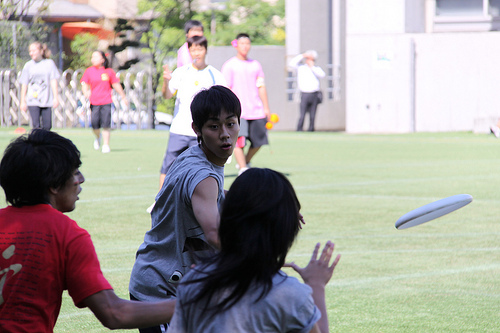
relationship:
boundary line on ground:
[326, 262, 499, 288] [1, 124, 499, 329]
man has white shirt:
[144, 22, 231, 214] [162, 59, 229, 136]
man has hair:
[2, 126, 176, 331] [0, 126, 82, 205]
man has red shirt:
[0, 127, 176, 333] [4, 200, 104, 317]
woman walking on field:
[125, 85, 238, 332] [0, 137, 499, 330]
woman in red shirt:
[80, 49, 129, 150] [78, 64, 118, 106]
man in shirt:
[225, 32, 265, 160] [225, 59, 264, 120]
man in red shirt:
[157, 34, 230, 192] [2, 203, 114, 330]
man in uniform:
[285, 51, 328, 128] [290, 55, 323, 127]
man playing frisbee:
[0, 127, 176, 333] [390, 194, 470, 231]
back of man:
[5, 208, 109, 305] [142, 66, 259, 301]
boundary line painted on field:
[325, 255, 499, 295] [340, 133, 497, 330]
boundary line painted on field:
[350, 240, 495, 256] [340, 133, 497, 330]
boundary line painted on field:
[98, 263, 137, 275] [340, 133, 497, 330]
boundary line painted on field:
[303, 205, 390, 217] [340, 133, 497, 330]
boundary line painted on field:
[298, 192, 433, 203] [340, 133, 497, 330]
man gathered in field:
[0, 127, 176, 333] [0, 137, 499, 330]